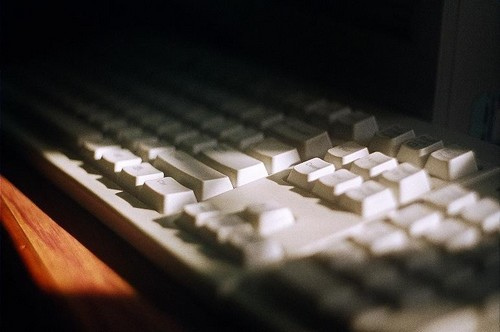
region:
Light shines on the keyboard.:
[135, 118, 455, 290]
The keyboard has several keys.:
[62, 95, 459, 268]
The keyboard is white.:
[35, 96, 478, 274]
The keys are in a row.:
[35, 80, 389, 217]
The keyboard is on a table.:
[2, 151, 187, 330]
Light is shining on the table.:
[2, 172, 153, 322]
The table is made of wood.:
[1, 169, 172, 323]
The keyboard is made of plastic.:
[50, 85, 490, 310]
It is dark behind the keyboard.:
[0, 0, 495, 131]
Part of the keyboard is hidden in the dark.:
[1, 33, 346, 139]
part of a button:
[224, 230, 249, 260]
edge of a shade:
[58, 270, 112, 302]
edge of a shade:
[117, 275, 174, 306]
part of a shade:
[84, 278, 114, 301]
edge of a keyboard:
[131, 222, 175, 297]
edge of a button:
[216, 150, 270, 205]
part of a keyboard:
[224, 278, 256, 315]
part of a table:
[63, 242, 105, 267]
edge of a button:
[198, 178, 228, 189]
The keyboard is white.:
[40, 51, 497, 326]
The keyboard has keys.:
[97, 104, 455, 311]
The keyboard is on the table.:
[33, 39, 430, 330]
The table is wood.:
[7, 187, 121, 320]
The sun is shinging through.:
[40, 76, 435, 329]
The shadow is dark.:
[34, 22, 493, 174]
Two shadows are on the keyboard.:
[23, 40, 431, 329]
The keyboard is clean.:
[34, 60, 485, 311]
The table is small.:
[14, 197, 116, 322]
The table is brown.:
[11, 198, 112, 323]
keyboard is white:
[0, 43, 495, 325]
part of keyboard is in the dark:
[8, 10, 498, 99]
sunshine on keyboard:
[17, 135, 493, 280]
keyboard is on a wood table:
[0, 15, 495, 325]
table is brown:
[1, 170, 148, 323]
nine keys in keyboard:
[283, 113, 483, 225]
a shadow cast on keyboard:
[264, 234, 499, 323]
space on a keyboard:
[281, 174, 332, 223]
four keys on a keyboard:
[176, 189, 296, 272]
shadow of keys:
[48, 170, 122, 216]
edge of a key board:
[360, 102, 400, 127]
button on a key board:
[345, 135, 360, 156]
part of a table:
[152, 310, 177, 312]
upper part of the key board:
[425, 113, 441, 135]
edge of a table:
[37, 250, 67, 280]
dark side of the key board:
[111, 93, 164, 115]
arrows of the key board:
[221, 216, 251, 236]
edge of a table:
[25, 260, 57, 295]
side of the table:
[37, 230, 77, 265]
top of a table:
[63, 221, 108, 228]